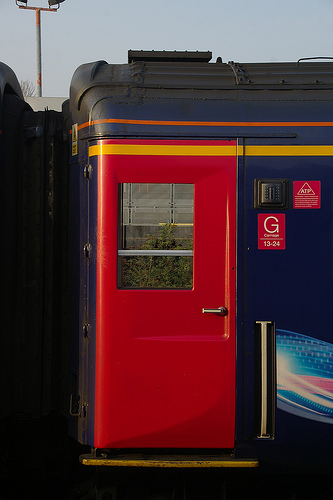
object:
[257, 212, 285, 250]
sign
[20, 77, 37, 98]
bare trees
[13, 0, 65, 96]
light pole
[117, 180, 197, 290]
window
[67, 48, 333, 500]
train car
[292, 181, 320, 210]
label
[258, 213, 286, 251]
label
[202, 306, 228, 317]
lever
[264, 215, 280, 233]
big g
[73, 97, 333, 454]
side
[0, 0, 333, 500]
photo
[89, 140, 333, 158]
yellow stripe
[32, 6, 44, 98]
woman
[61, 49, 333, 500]
car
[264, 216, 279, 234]
letter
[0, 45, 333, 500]
train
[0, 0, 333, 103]
sky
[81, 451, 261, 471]
platform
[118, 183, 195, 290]
tree reflection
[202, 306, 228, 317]
handle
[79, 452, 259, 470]
step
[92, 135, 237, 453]
door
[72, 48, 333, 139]
roof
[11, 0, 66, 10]
flood lights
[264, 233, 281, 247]
letters